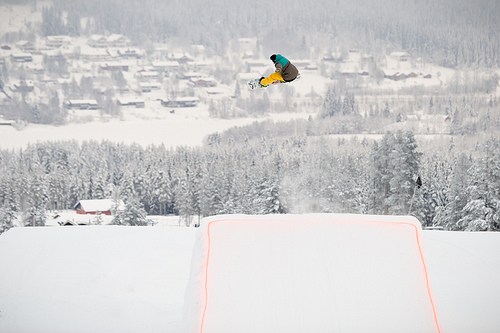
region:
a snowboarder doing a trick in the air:
[240, 53, 313, 94]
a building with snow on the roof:
[62, 195, 127, 218]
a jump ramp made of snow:
[175, 208, 449, 326]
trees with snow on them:
[380, 140, 446, 200]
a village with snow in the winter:
[44, 31, 195, 114]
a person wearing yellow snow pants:
[258, 69, 285, 88]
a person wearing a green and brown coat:
[270, 50, 298, 80]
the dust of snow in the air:
[278, 173, 336, 211]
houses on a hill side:
[51, 33, 177, 108]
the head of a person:
[266, 53, 281, 62]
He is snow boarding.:
[228, 52, 323, 109]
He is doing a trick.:
[237, 60, 326, 105]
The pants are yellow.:
[250, 70, 283, 90]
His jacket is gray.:
[268, 57, 300, 83]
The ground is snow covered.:
[24, 215, 497, 330]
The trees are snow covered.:
[0, 123, 494, 226]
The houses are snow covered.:
[5, 27, 421, 113]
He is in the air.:
[28, 55, 489, 315]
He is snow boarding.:
[0, 6, 486, 318]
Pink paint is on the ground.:
[185, 213, 445, 332]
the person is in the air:
[246, 53, 298, 91]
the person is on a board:
[245, 53, 297, 88]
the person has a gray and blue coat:
[278, 55, 298, 80]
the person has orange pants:
[259, 70, 284, 85]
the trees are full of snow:
[0, 0, 498, 232]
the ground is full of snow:
[2, 213, 498, 331]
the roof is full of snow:
[66, 196, 123, 214]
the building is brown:
[74, 206, 116, 212]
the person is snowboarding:
[247, 55, 296, 89]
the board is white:
[245, 76, 261, 91]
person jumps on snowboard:
[243, 45, 320, 109]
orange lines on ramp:
[210, 205, 404, 332]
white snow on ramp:
[154, 223, 429, 332]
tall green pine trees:
[56, 106, 493, 233]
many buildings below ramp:
[19, 19, 401, 149]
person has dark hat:
[272, 48, 275, 71]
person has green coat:
[274, 49, 294, 69]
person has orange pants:
[257, 65, 289, 91]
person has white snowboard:
[242, 75, 275, 85]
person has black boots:
[250, 84, 280, 95]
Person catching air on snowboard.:
[245, 53, 305, 93]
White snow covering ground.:
[7, 228, 165, 330]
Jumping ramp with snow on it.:
[180, 210, 450, 331]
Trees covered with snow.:
[7, 141, 494, 203]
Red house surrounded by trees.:
[73, 200, 123, 217]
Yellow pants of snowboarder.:
[253, 72, 282, 88]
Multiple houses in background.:
[3, 23, 223, 121]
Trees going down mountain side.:
[66, 0, 495, 56]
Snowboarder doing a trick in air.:
[235, 47, 312, 103]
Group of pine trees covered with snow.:
[5, 142, 229, 201]